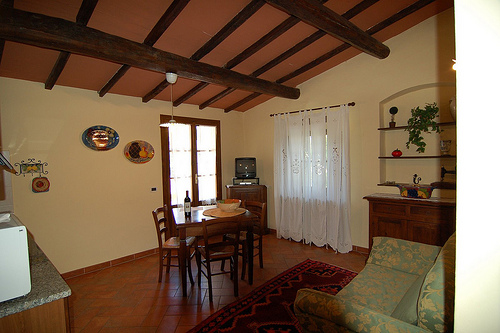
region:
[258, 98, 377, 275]
long sheer white curtains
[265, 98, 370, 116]
long slim gold curtain rod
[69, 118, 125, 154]
gray decorative plate on wall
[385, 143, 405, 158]
small orange vase on shelf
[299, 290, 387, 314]
gold and green arm on love seat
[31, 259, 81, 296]
stone top of counter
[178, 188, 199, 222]
tall green bottle of wine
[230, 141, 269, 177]
small television on table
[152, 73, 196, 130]
light fixture hanging from ceiling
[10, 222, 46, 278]
side of white microwave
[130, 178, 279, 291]
Table and chairs in the center of the room.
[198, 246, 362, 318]
A rug in front of the chair.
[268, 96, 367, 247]
Curtains on the window.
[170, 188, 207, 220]
A wine bottle on the table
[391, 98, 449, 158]
A plant on the shelf.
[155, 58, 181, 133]
Light hanging from the ceiling.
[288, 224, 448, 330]
A chair on the rug.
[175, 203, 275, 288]
Chairs under the table.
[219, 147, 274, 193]
A television in the corner.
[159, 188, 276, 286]
The table and chairs are wooden.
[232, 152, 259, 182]
Small black television next to white curtain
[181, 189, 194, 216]
Wine bottle on table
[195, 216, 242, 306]
Wooden chair next to rug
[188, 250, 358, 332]
Rug in front of sofa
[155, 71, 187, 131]
White light hanging from wooden beam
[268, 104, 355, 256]
White curtain on black rod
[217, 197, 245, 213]
Bowl on wooden table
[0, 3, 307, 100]
Wooden beam on ceiling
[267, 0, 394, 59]
Wooden beam above rug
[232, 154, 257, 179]
Small television on top of wooden media center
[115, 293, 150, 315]
tiles on the floor.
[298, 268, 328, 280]
rug on the floor.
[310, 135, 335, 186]
curtains on the window.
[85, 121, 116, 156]
plate on the wall.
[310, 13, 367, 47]
support beam made of wood.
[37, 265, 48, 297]
counter top made of granite.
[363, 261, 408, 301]
chair in the room.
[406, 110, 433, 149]
plant on the shelf.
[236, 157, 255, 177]
television in the room.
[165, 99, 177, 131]
light hanging from ceiling.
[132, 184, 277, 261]
Dining room table with chairs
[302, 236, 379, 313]
Floral sofa on carpet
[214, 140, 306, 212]
TV on a TV stand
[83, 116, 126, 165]
Plate on a wall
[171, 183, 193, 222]
Bottle on top of a table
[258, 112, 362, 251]
White curtain on a window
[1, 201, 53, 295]
Microwave on a counter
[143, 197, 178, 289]
Chair in front of a table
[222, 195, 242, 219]
Bowl on a table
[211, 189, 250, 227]
Bowl on a table